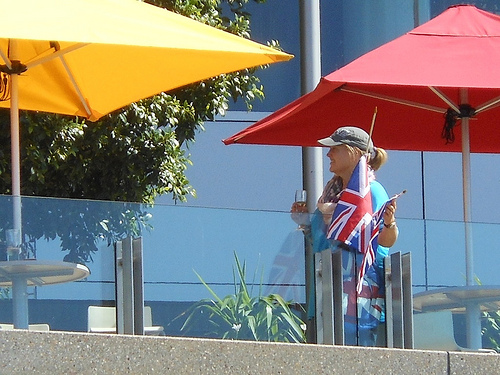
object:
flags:
[326, 154, 373, 255]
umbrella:
[221, 3, 500, 155]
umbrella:
[0, 0, 294, 122]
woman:
[291, 124, 400, 347]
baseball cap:
[318, 126, 374, 155]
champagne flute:
[295, 190, 308, 231]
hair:
[345, 143, 389, 172]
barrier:
[0, 193, 499, 353]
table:
[414, 285, 499, 351]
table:
[0, 260, 91, 330]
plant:
[166, 249, 306, 342]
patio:
[0, 193, 498, 373]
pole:
[460, 88, 472, 289]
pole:
[8, 41, 23, 259]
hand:
[290, 203, 309, 225]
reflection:
[262, 231, 306, 303]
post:
[299, 2, 325, 344]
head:
[326, 126, 373, 174]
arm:
[368, 180, 399, 248]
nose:
[326, 150, 332, 157]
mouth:
[330, 158, 336, 164]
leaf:
[191, 268, 232, 312]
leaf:
[189, 190, 197, 200]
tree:
[0, 0, 284, 283]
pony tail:
[368, 146, 388, 171]